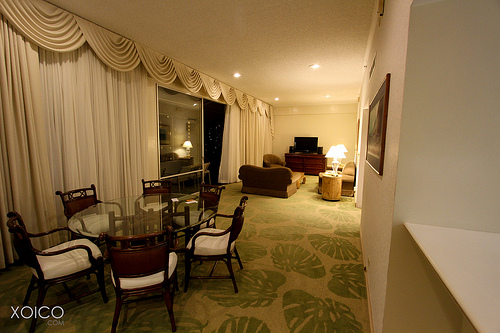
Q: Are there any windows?
A: Yes, there is a window.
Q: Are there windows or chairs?
A: Yes, there is a window.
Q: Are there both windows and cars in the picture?
A: No, there is a window but no cars.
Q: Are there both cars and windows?
A: No, there is a window but no cars.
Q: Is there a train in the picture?
A: No, there are no trains.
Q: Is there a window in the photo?
A: Yes, there are windows.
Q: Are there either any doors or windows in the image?
A: Yes, there are windows.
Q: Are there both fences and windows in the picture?
A: No, there are windows but no fences.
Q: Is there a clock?
A: No, there are no clocks.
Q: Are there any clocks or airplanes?
A: No, there are no clocks or airplanes.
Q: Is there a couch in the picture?
A: Yes, there is a couch.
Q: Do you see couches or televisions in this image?
A: Yes, there is a couch.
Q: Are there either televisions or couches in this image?
A: Yes, there is a couch.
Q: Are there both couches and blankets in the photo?
A: No, there is a couch but no blankets.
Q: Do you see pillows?
A: No, there are no pillows.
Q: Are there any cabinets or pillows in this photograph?
A: No, there are no pillows or cabinets.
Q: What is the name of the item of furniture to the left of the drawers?
A: The piece of furniture is a couch.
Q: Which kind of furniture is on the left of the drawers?
A: The piece of furniture is a couch.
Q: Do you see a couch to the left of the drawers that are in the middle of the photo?
A: Yes, there is a couch to the left of the drawers.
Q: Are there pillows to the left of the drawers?
A: No, there is a couch to the left of the drawers.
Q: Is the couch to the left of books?
A: No, the couch is to the left of the drawers.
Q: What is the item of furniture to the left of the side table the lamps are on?
A: The piece of furniture is a couch.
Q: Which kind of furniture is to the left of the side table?
A: The piece of furniture is a couch.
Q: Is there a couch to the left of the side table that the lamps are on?
A: Yes, there is a couch to the left of the side table.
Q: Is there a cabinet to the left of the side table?
A: No, there is a couch to the left of the side table.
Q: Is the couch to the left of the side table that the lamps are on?
A: Yes, the couch is to the left of the side table.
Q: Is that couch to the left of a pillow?
A: No, the couch is to the left of the side table.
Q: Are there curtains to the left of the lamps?
A: Yes, there are curtains to the left of the lamps.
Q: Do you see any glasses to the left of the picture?
A: No, there are curtains to the left of the picture.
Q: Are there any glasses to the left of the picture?
A: No, there are curtains to the left of the picture.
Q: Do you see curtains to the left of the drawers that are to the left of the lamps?
A: Yes, there are curtains to the left of the drawers.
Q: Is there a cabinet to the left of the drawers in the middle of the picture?
A: No, there are curtains to the left of the drawers.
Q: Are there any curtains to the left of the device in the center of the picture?
A: Yes, there are curtains to the left of the TV.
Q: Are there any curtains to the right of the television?
A: No, the curtains are to the left of the television.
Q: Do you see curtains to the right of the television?
A: No, the curtains are to the left of the television.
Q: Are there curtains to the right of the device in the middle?
A: No, the curtains are to the left of the television.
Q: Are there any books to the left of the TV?
A: No, there are curtains to the left of the TV.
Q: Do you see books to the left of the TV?
A: No, there are curtains to the left of the TV.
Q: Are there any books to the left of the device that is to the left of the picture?
A: No, there are curtains to the left of the TV.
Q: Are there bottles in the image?
A: No, there are no bottles.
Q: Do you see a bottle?
A: No, there are no bottles.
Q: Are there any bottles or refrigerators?
A: No, there are no bottles or refrigerators.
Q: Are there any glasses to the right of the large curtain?
A: No, there are drawers to the right of the curtain.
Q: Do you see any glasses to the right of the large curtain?
A: No, there are drawers to the right of the curtain.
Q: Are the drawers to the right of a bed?
A: No, the drawers are to the right of the curtain.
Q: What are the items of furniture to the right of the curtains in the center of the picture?
A: The pieces of furniture are drawers.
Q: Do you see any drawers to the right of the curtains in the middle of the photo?
A: Yes, there are drawers to the right of the curtains.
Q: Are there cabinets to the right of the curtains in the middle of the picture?
A: No, there are drawers to the right of the curtains.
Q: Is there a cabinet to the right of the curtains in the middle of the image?
A: No, there are drawers to the right of the curtains.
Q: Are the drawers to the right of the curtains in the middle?
A: Yes, the drawers are to the right of the curtains.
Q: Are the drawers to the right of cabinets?
A: No, the drawers are to the right of the curtains.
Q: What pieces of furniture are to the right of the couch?
A: The pieces of furniture are drawers.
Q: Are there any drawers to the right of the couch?
A: Yes, there are drawers to the right of the couch.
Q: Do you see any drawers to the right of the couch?
A: Yes, there are drawers to the right of the couch.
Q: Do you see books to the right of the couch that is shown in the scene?
A: No, there are drawers to the right of the couch.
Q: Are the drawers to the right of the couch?
A: Yes, the drawers are to the right of the couch.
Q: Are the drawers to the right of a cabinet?
A: No, the drawers are to the right of the couch.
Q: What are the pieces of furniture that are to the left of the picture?
A: The pieces of furniture are drawers.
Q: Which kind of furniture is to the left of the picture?
A: The pieces of furniture are drawers.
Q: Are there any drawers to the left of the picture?
A: Yes, there are drawers to the left of the picture.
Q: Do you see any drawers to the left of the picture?
A: Yes, there are drawers to the left of the picture.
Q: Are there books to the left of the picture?
A: No, there are drawers to the left of the picture.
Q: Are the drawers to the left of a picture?
A: Yes, the drawers are to the left of a picture.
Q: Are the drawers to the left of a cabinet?
A: No, the drawers are to the left of a picture.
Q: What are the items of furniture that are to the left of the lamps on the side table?
A: The pieces of furniture are drawers.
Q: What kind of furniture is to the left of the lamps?
A: The pieces of furniture are drawers.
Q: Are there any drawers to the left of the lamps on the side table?
A: Yes, there are drawers to the left of the lamps.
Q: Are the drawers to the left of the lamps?
A: Yes, the drawers are to the left of the lamps.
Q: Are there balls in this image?
A: No, there are no balls.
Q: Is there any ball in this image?
A: No, there are no balls.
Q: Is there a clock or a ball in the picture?
A: No, there are no balls or clocks.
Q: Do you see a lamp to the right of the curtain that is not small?
A: Yes, there are lamps to the right of the curtain.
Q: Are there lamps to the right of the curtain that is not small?
A: Yes, there are lamps to the right of the curtain.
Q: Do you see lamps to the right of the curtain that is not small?
A: Yes, there are lamps to the right of the curtain.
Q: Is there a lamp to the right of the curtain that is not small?
A: Yes, there are lamps to the right of the curtain.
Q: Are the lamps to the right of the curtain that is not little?
A: Yes, the lamps are to the right of the curtain.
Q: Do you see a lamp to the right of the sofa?
A: Yes, there are lamps to the right of the sofa.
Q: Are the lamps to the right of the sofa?
A: Yes, the lamps are to the right of the sofa.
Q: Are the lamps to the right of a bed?
A: No, the lamps are to the right of the sofa.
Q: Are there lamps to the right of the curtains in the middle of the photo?
A: Yes, there are lamps to the right of the curtains.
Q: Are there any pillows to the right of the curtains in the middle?
A: No, there are lamps to the right of the curtains.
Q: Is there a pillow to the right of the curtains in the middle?
A: No, there are lamps to the right of the curtains.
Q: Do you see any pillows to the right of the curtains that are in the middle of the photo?
A: No, there are lamps to the right of the curtains.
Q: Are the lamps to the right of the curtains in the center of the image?
A: Yes, the lamps are to the right of the curtains.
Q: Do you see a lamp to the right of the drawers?
A: Yes, there are lamps to the right of the drawers.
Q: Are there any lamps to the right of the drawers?
A: Yes, there are lamps to the right of the drawers.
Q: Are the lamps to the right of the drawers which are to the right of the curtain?
A: Yes, the lamps are to the right of the drawers.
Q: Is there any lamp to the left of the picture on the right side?
A: Yes, there are lamps to the left of the picture.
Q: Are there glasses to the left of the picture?
A: No, there are lamps to the left of the picture.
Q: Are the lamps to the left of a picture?
A: Yes, the lamps are to the left of a picture.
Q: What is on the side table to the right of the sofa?
A: The lamps are on the side table.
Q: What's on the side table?
A: The lamps are on the side table.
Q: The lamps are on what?
A: The lamps are on the side table.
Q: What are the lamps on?
A: The lamps are on the side table.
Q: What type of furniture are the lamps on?
A: The lamps are on the side table.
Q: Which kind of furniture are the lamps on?
A: The lamps are on the side table.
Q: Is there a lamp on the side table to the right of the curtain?
A: Yes, there are lamps on the side table.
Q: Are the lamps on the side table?
A: Yes, the lamps are on the side table.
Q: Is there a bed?
A: No, there are no beds.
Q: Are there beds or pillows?
A: No, there are no beds or pillows.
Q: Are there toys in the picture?
A: No, there are no toys.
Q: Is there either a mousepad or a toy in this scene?
A: No, there are no toys or mouse pads.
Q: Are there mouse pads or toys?
A: No, there are no toys or mouse pads.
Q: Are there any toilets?
A: No, there are no toilets.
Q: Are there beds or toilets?
A: No, there are no toilets or beds.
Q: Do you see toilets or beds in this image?
A: No, there are no toilets or beds.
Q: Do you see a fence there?
A: No, there are no fences.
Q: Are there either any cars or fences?
A: No, there are no fences or cars.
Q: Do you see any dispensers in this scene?
A: No, there are no dispensers.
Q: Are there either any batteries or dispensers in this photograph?
A: No, there are no dispensers or batteries.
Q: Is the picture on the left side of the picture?
A: No, the picture is on the right of the image.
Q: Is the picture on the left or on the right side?
A: The picture is on the right of the image.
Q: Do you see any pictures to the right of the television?
A: Yes, there is a picture to the right of the television.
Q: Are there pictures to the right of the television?
A: Yes, there is a picture to the right of the television.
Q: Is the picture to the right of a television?
A: Yes, the picture is to the right of a television.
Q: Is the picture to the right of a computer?
A: No, the picture is to the right of a television.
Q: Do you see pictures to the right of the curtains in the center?
A: Yes, there is a picture to the right of the curtains.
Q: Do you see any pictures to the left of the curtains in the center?
A: No, the picture is to the right of the curtains.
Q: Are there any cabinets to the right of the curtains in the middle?
A: No, there is a picture to the right of the curtains.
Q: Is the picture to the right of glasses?
A: No, the picture is to the right of the curtains.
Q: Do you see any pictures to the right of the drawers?
A: Yes, there is a picture to the right of the drawers.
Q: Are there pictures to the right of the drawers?
A: Yes, there is a picture to the right of the drawers.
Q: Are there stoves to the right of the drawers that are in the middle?
A: No, there is a picture to the right of the drawers.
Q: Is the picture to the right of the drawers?
A: Yes, the picture is to the right of the drawers.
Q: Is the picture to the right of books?
A: No, the picture is to the right of the drawers.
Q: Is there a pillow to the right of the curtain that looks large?
A: No, there is a picture to the right of the curtain.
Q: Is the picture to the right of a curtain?
A: Yes, the picture is to the right of a curtain.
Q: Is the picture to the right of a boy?
A: No, the picture is to the right of a curtain.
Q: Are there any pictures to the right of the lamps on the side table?
A: Yes, there is a picture to the right of the lamps.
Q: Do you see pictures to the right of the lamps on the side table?
A: Yes, there is a picture to the right of the lamps.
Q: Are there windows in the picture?
A: Yes, there is a window.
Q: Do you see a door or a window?
A: Yes, there is a window.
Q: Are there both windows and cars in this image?
A: No, there is a window but no cars.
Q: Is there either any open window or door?
A: Yes, there is an open window.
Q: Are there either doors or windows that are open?
A: Yes, the window is open.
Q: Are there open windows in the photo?
A: Yes, there is an open window.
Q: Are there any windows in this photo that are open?
A: Yes, there is a window that is open.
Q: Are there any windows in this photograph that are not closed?
A: Yes, there is a open window.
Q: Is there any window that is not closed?
A: Yes, there is a open window.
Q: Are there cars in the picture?
A: No, there are no cars.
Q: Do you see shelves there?
A: No, there are no shelves.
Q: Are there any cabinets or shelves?
A: No, there are no shelves or cabinets.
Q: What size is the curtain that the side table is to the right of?
A: The curtain is large.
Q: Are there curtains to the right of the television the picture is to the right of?
A: No, the curtain is to the left of the TV.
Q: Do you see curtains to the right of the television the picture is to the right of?
A: No, the curtain is to the left of the TV.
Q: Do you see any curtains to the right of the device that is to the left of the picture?
A: No, the curtain is to the left of the TV.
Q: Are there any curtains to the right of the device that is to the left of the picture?
A: No, the curtain is to the left of the TV.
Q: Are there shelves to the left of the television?
A: No, there is a curtain to the left of the television.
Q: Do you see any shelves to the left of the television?
A: No, there is a curtain to the left of the television.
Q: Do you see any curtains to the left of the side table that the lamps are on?
A: Yes, there is a curtain to the left of the side table.